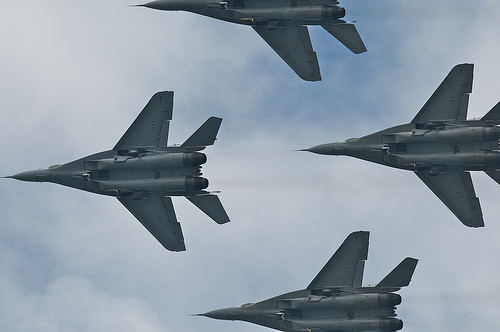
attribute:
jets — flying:
[13, 5, 492, 324]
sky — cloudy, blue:
[2, 2, 499, 331]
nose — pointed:
[1, 169, 47, 191]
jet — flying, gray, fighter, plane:
[3, 85, 240, 268]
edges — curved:
[94, 116, 138, 155]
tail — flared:
[176, 107, 239, 231]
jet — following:
[280, 50, 499, 245]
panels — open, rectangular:
[110, 148, 144, 165]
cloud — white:
[2, 4, 204, 139]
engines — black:
[179, 149, 213, 192]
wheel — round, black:
[427, 167, 442, 176]